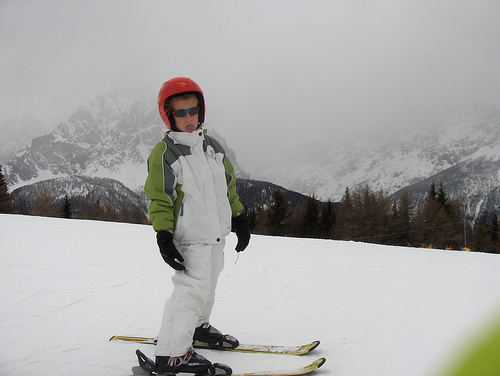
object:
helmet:
[158, 76, 206, 130]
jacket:
[142, 130, 243, 246]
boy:
[144, 76, 250, 375]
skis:
[102, 329, 324, 375]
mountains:
[8, 61, 250, 217]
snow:
[0, 211, 499, 376]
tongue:
[183, 124, 195, 136]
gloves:
[155, 231, 186, 271]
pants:
[152, 240, 225, 360]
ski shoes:
[153, 350, 214, 374]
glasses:
[170, 108, 201, 118]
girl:
[144, 73, 251, 374]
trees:
[57, 193, 74, 218]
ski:
[97, 348, 328, 374]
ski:
[107, 333, 322, 356]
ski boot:
[194, 323, 239, 350]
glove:
[233, 214, 248, 252]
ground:
[0, 214, 492, 355]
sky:
[0, 3, 497, 76]